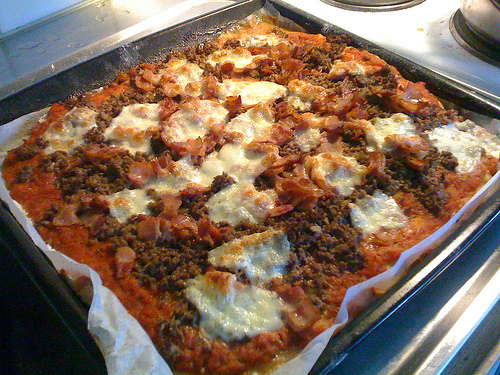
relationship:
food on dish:
[4, 15, 498, 373] [0, 0, 500, 374]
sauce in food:
[3, 153, 227, 373] [8, 6, 484, 348]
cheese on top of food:
[175, 272, 294, 344] [4, 15, 498, 373]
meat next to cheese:
[287, 203, 350, 265] [207, 236, 283, 329]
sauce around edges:
[3, 153, 227, 373] [124, 347, 333, 373]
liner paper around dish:
[84, 283, 175, 372] [9, 3, 499, 374]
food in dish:
[4, 15, 498, 373] [9, 3, 499, 374]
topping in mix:
[306, 220, 356, 275] [5, 13, 482, 361]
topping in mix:
[348, 188, 408, 234] [5, 13, 482, 361]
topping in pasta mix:
[296, 207, 355, 259] [27, 16, 484, 366]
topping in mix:
[387, 154, 454, 214] [5, 13, 482, 361]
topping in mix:
[161, 250, 178, 266] [23, 30, 483, 356]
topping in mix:
[206, 187, 328, 290] [11, 23, 451, 345]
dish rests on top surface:
[9, 3, 499, 374] [0, 0, 236, 93]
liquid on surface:
[18, 37, 45, 52] [32, 17, 89, 52]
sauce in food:
[161, 97, 235, 139] [4, 15, 498, 373]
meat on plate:
[99, 216, 210, 282] [127, 7, 226, 78]